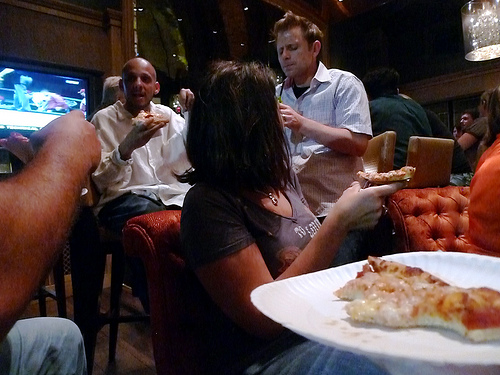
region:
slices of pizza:
[340, 254, 498, 342]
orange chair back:
[390, 186, 487, 253]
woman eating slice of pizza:
[177, 58, 418, 374]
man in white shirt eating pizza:
[86, 56, 195, 209]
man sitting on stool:
[83, 56, 198, 373]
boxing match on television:
[2, 65, 94, 136]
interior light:
[465, 1, 497, 62]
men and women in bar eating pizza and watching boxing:
[1, 10, 498, 373]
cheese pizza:
[338, 255, 497, 340]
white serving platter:
[246, 249, 497, 364]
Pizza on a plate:
[311, 258, 498, 354]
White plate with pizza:
[268, 259, 498, 362]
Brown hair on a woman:
[194, 59, 291, 209]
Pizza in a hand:
[127, 106, 172, 140]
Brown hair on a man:
[262, 12, 338, 95]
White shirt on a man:
[93, 98, 198, 208]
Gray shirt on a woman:
[177, 178, 330, 275]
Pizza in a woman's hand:
[346, 164, 413, 219]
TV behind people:
[5, 63, 92, 140]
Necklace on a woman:
[262, 190, 276, 202]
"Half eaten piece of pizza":
[334, 254, 498, 346]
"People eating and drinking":
[5, 10, 496, 372]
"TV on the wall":
[0, 60, 97, 137]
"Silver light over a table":
[460, 0, 497, 64]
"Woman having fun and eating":
[171, 60, 421, 365]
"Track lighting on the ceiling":
[136, 3, 331, 70]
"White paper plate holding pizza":
[247, 247, 498, 369]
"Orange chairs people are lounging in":
[114, 185, 495, 371]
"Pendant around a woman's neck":
[264, 189, 284, 208]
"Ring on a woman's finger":
[380, 202, 391, 215]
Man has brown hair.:
[273, 13, 335, 38]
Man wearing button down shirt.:
[286, 80, 308, 171]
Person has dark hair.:
[203, 68, 252, 149]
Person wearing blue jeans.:
[286, 355, 319, 372]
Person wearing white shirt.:
[96, 110, 165, 164]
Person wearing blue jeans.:
[114, 200, 148, 212]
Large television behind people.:
[5, 65, 87, 106]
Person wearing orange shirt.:
[473, 166, 494, 232]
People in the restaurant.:
[80, 50, 490, 272]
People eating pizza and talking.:
[98, 30, 418, 227]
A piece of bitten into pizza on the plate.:
[319, 243, 485, 343]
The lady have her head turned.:
[184, 59, 296, 192]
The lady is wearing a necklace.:
[231, 179, 299, 209]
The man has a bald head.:
[101, 48, 166, 78]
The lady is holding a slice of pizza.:
[340, 158, 404, 198]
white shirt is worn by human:
[275, 60, 379, 217]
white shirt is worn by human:
[87, 99, 196, 213]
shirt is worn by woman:
[178, 166, 330, 281]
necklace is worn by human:
[265, 191, 281, 209]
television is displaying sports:
[0, 52, 110, 137]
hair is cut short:
[273, 9, 325, 62]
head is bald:
[114, 55, 164, 110]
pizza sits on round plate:
[340, 253, 499, 343]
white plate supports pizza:
[247, 247, 499, 372]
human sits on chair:
[360, 67, 469, 174]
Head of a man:
[116, 57, 161, 109]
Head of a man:
[271, 11, 329, 83]